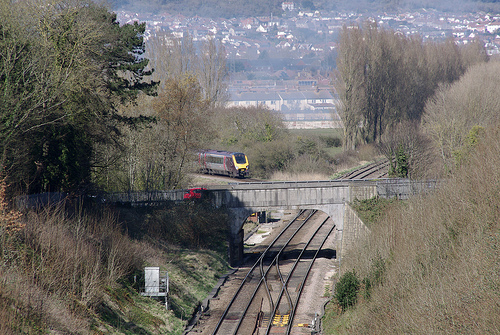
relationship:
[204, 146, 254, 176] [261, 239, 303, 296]
train on tracks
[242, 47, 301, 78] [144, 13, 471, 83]
hillside of a buildings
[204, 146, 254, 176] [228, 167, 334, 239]
train are at a crossway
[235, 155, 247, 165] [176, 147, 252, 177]
window on train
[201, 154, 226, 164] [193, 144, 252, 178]
windows on train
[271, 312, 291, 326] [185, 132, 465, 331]
tool on track